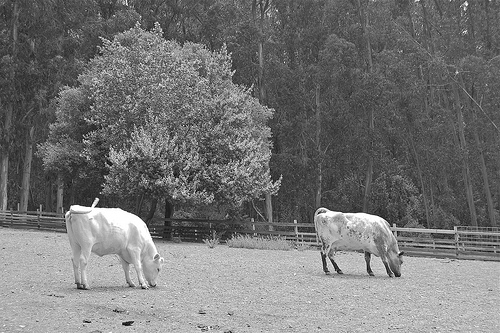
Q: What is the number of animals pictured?
A: Two.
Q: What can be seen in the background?
A: A forest.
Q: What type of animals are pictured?
A: Cow.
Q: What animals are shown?
A: Cows.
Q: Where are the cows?
A: In a corral.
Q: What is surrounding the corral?
A: A wooden fence.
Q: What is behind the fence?
A: Trees.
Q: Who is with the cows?
A: Nobody.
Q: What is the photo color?
A: Black and white.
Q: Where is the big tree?
A: Just outside the fence.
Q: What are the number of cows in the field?
A: 2.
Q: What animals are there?
A: Cows.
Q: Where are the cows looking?
A: Down.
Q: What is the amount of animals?
A: Two.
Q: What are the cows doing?
A: Grazing.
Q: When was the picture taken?
A: Daytime.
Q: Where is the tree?
A: Behind the cows.